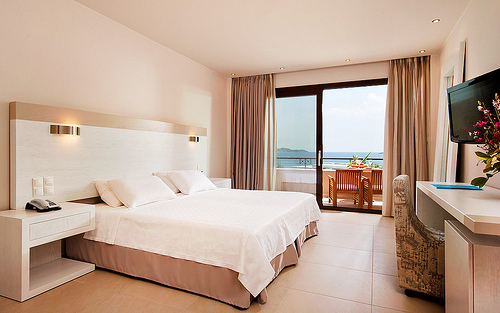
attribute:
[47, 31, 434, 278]
room — hotel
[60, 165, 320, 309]
bed — king size, made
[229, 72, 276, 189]
curtain — tan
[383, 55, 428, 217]
curtain — tan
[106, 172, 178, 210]
pillow — white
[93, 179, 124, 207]
pillow — white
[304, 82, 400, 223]
door — glass door, sliding door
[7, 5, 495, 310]
room — very clean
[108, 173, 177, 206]
pillow — white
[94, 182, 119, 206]
pillow — white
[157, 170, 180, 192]
pillow — white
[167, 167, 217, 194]
pillow — white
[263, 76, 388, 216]
doors — sliding, glass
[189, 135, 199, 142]
light — on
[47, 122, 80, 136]
light — on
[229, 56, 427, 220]
curtains — hanging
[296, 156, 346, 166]
water — view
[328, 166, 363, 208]
chair — wooden, outdoor chair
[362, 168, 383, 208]
chair — wooden, outdoor chair